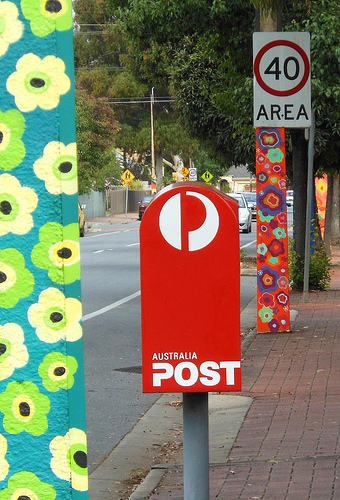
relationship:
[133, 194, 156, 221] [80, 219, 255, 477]
car parked beside street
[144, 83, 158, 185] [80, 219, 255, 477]
pole beside street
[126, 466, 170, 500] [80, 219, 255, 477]
curb between street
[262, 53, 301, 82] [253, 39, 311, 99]
number inside of circle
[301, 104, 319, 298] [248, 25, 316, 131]
pole behind sign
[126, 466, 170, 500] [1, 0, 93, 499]
curb next to post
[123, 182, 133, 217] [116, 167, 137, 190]
post under street sign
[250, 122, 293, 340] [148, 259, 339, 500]
post touching side walk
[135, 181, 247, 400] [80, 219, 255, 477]
sign beside street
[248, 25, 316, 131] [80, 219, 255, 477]
sign on street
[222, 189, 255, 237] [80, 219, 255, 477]
car on street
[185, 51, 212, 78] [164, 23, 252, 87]
leaves growing on branches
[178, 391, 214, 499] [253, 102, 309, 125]
post supporting letters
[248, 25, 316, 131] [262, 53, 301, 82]
sign posting number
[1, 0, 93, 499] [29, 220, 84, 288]
post has flower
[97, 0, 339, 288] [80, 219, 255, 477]
tree overhanging street